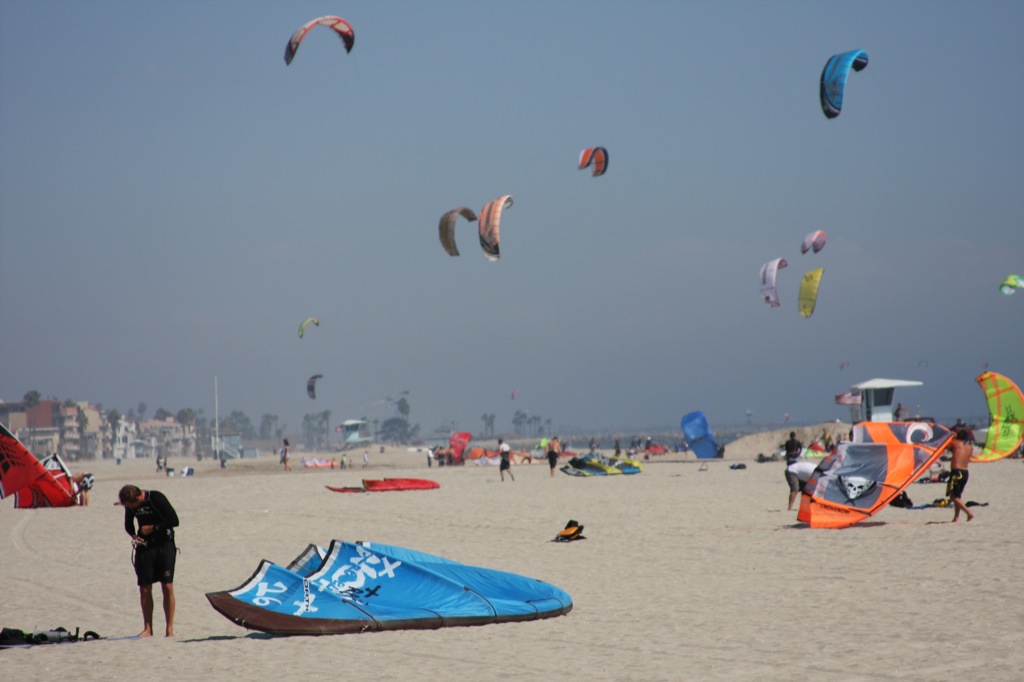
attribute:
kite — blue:
[678, 404, 724, 465]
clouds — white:
[125, 146, 352, 317]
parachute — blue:
[195, 520, 582, 639]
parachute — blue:
[195, 524, 593, 654]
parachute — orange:
[784, 408, 951, 538]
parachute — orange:
[791, 412, 936, 538]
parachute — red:
[2, 423, 87, 519]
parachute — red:
[6, 419, 106, 523]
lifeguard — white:
[847, 363, 936, 422]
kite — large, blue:
[810, 32, 877, 125]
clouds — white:
[43, 125, 322, 367]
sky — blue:
[13, 10, 1022, 430]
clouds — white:
[162, 241, 288, 371]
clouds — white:
[142, 173, 249, 247]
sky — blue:
[45, 61, 421, 370]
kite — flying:
[417, 175, 541, 292]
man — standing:
[78, 415, 245, 675]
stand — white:
[853, 369, 921, 430]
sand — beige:
[675, 568, 781, 627]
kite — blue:
[235, 527, 564, 636]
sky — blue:
[158, 63, 481, 386]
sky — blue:
[393, 208, 789, 429]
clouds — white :
[257, 173, 478, 338]